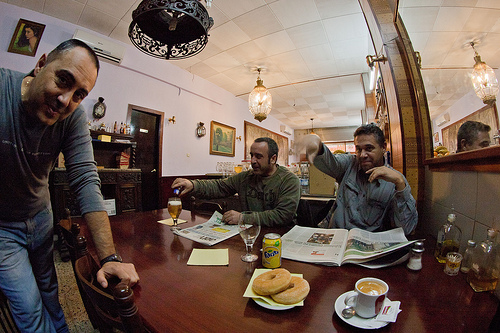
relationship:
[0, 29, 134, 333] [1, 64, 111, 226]
man standing shirt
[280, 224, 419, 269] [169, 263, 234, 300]
newspaper on a table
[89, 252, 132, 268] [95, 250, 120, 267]
watch on wrist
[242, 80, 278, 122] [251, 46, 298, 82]
light hangs from ceiling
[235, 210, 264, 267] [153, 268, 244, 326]
empty glass on table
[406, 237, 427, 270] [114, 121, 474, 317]
shaker on table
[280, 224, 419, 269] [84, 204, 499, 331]
newspaper on table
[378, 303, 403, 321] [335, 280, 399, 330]
sugar on coffee dish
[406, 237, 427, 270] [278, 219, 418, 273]
shaker by newspaper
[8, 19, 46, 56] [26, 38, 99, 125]
painting behind head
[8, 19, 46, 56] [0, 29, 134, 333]
painting behind man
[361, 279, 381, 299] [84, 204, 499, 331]
coffee on table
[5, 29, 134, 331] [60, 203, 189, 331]
man leaning against table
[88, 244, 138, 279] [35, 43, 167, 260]
watch on man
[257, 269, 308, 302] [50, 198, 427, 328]
bagel sitting on table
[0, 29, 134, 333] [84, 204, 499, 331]
man standing by table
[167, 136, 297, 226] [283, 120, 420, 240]
man sitting at a man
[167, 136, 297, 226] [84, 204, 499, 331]
man sitting at a table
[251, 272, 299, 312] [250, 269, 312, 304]
plate of donuts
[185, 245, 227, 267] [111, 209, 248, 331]
napkin on table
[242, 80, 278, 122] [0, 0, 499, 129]
light hanging from ceiling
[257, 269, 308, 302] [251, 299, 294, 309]
bagel on plate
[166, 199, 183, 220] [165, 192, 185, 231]
beer in glass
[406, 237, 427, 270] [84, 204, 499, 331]
shaker on table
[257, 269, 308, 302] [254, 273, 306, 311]
bagel on plate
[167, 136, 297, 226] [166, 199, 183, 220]
man pouring beer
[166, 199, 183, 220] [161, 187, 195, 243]
beer in glass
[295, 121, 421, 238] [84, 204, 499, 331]
man sitting at table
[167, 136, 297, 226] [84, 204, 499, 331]
man sitting at table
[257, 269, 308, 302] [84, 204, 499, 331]
bagel sitting on table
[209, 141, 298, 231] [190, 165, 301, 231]
man wearing shirt